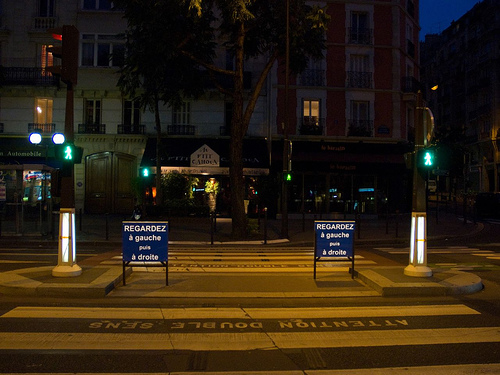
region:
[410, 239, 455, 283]
White light inside of a statue.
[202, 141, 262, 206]
White light inside of a statue.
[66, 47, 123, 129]
White light inside of a statue.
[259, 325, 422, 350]
the stripe is white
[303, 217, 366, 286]
the sign is blue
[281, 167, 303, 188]
the light is green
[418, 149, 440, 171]
the light is blue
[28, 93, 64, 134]
the building has a window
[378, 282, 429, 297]
the curb is white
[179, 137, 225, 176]
the sign is on the awning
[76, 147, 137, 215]
the door is closed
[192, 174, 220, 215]
the light is yellow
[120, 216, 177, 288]
this is a sign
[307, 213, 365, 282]
this is a sign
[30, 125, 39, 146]
this is a light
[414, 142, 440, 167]
this is a light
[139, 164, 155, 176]
this is a light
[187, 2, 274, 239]
this is a tree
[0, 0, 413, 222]
this is a buliding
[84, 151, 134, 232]
the door of a building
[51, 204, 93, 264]
this is a pillar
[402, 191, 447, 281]
this is a pillar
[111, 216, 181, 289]
blue sign on street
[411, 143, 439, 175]
green human figure on pedestrian traffic light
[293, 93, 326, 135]
window on building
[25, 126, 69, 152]
two white glove street lamps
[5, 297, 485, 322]
white stripe painted on street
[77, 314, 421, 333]
words in white print on street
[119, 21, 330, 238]
tall tree on sidewalk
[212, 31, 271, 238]
brown tree trunk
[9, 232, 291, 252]
street curb